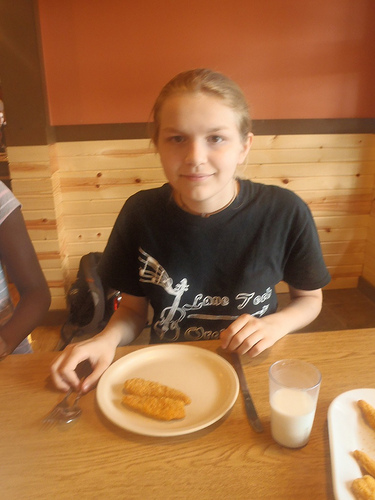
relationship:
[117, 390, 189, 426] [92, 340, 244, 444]
chicken strip on plate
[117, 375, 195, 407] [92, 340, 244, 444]
chicken strip on plate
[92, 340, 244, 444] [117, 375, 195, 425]
plate has chicken strips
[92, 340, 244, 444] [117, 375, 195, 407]
plate has chicken strip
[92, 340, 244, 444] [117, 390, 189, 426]
plate has chicken strip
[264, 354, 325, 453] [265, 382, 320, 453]
cup with milk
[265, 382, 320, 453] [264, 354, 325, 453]
milk in cup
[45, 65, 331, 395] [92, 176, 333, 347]
girl wearing shirt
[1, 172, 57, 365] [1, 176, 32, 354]
girl wearing shirt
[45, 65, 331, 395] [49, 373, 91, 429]
girl holding spoon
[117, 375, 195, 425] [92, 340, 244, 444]
chicken fingers on plate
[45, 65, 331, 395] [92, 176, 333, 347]
girl in shirt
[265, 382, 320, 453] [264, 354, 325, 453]
milk in glass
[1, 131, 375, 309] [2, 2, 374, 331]
paneling in background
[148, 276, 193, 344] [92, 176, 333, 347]
violin on shirt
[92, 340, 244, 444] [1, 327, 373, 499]
plate on table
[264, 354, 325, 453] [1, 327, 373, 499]
glass on top of table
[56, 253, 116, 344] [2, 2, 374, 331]
backpack in back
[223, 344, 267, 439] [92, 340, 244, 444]
knife right of plate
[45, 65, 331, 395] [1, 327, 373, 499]
girl sitting at table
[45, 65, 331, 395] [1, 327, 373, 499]
girl at table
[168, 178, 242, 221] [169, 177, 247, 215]
necklace on neck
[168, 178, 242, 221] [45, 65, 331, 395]
necklace on girl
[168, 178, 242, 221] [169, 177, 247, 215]
necklace around neck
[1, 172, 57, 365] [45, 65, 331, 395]
person sitting next to girl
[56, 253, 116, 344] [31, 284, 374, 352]
backpack on floor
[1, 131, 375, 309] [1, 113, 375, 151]
wall beneath chair-rail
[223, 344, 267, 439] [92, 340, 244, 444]
knife next to plate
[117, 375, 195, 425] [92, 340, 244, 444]
chicken tenders on a plate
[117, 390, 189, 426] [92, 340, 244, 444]
chicken tender on a plate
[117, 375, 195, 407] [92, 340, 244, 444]
chicken tender on a plate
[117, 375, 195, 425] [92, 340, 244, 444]
chicken fingers on a plate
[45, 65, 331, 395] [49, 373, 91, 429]
girl reaching for utensil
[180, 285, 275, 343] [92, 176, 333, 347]
wording on shirt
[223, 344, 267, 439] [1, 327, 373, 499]
knife on top of table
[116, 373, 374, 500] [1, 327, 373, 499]
food on top of table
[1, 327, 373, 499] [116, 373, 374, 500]
table holding food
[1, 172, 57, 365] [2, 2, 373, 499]
girl out of shot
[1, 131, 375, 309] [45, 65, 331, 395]
wall behind girl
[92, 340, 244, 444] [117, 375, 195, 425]
plate holding chicken fingers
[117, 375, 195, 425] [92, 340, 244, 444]
chicken fingers on top of plate